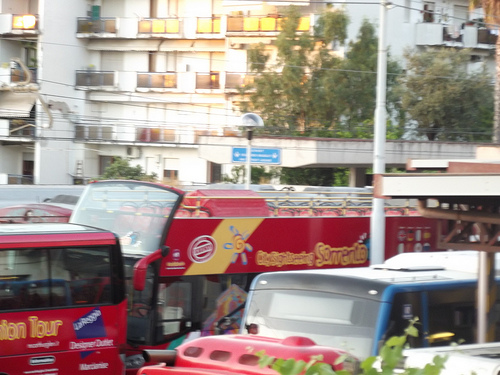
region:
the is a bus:
[61, 123, 462, 346]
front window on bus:
[73, 169, 170, 341]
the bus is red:
[87, 170, 388, 372]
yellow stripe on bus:
[177, 212, 268, 287]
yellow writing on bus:
[248, 221, 374, 278]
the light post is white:
[372, 60, 384, 270]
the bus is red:
[171, 201, 366, 268]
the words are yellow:
[255, 242, 383, 273]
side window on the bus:
[162, 276, 195, 328]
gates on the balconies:
[86, 117, 224, 143]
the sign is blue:
[235, 140, 290, 167]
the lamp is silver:
[241, 112, 263, 131]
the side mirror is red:
[131, 255, 159, 287]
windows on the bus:
[5, 244, 123, 315]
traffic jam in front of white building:
[8, 12, 488, 366]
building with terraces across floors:
[7, 5, 497, 148]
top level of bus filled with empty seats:
[77, 175, 442, 280]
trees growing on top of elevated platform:
[197, 7, 496, 174]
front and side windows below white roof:
[238, 248, 494, 354]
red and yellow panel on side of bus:
[163, 213, 439, 276]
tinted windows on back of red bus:
[5, 217, 130, 370]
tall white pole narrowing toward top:
[367, 4, 393, 264]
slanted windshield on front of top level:
[71, 175, 186, 260]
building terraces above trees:
[409, 5, 496, 95]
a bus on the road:
[276, 242, 465, 369]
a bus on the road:
[96, 159, 397, 344]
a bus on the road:
[4, 205, 159, 369]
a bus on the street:
[229, 241, 499, 373]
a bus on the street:
[98, 183, 370, 366]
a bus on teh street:
[18, 213, 143, 362]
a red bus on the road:
[83, 178, 378, 372]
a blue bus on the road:
[243, 244, 489, 362]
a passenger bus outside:
[167, 160, 390, 330]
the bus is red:
[81, 144, 465, 354]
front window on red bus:
[66, 165, 176, 362]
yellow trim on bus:
[183, 203, 252, 292]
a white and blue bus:
[234, 204, 475, 372]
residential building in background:
[9, 7, 476, 238]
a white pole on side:
[359, 6, 411, 283]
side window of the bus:
[1, 235, 130, 325]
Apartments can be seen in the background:
[2, 2, 489, 215]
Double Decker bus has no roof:
[62, 171, 479, 366]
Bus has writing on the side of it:
[142, 215, 469, 277]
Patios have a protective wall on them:
[63, 2, 342, 197]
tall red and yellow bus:
[71, 167, 452, 374]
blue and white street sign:
[228, 142, 288, 167]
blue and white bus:
[239, 250, 497, 373]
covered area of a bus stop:
[372, 150, 499, 361]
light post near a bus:
[236, 106, 263, 186]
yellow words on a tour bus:
[0, 315, 64, 345]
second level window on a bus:
[75, 178, 178, 257]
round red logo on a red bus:
[186, 231, 218, 269]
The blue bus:
[226, 239, 498, 364]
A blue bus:
[231, 235, 498, 359]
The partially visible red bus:
[0, 215, 140, 370]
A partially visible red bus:
[1, 210, 142, 372]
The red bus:
[77, 167, 479, 355]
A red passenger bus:
[64, 163, 466, 345]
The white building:
[2, 57, 324, 197]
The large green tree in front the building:
[220, 61, 415, 188]